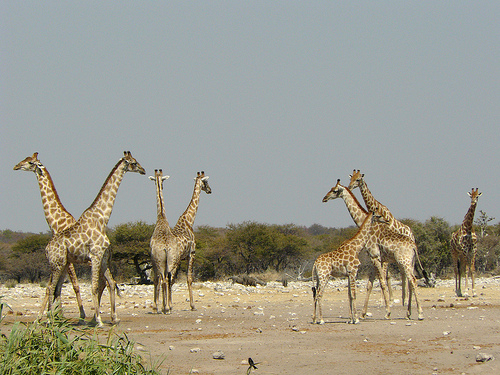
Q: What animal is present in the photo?
A: Giraffe.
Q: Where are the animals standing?
A: On the sand.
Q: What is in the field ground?
A: A patch of grass.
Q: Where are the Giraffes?
A: Across the row of trees.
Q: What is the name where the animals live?
A: In the wild.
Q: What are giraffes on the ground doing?
A: They are standing.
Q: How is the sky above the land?
A: It is blue.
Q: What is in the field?
A: A herd of eight giraffes.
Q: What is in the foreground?
A: Shrubs.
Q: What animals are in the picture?
A: Giraffes.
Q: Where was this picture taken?
A: A safari.